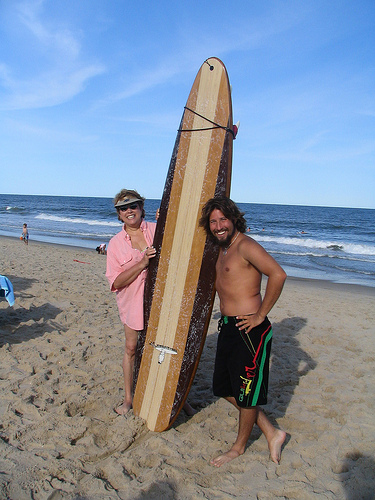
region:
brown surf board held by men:
[163, 56, 198, 415]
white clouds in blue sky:
[22, 7, 100, 72]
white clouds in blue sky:
[0, 60, 59, 114]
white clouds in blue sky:
[25, 114, 57, 159]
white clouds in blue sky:
[58, 100, 127, 163]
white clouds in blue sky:
[107, 41, 161, 110]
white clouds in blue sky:
[167, 9, 227, 49]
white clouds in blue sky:
[263, 8, 341, 75]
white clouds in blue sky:
[262, 71, 347, 154]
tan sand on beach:
[23, 419, 117, 474]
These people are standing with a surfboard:
[111, 46, 234, 344]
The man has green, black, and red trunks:
[218, 326, 280, 404]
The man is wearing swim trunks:
[211, 308, 289, 417]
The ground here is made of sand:
[10, 407, 176, 491]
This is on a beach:
[13, 329, 369, 495]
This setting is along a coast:
[13, 140, 339, 410]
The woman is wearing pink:
[82, 221, 188, 301]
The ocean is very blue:
[41, 192, 367, 292]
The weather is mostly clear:
[23, 6, 318, 153]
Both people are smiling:
[111, 197, 248, 260]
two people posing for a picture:
[72, 159, 297, 464]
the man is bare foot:
[193, 383, 301, 475]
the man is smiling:
[192, 186, 254, 258]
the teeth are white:
[208, 227, 235, 240]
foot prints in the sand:
[25, 396, 236, 496]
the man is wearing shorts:
[197, 292, 290, 425]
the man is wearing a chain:
[201, 225, 248, 264]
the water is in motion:
[278, 208, 353, 271]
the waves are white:
[291, 227, 364, 265]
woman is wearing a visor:
[89, 170, 154, 246]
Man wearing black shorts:
[209, 306, 277, 431]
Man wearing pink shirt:
[100, 222, 153, 339]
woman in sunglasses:
[113, 200, 146, 220]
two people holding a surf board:
[160, 131, 238, 357]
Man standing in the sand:
[199, 326, 295, 497]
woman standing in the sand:
[109, 306, 158, 429]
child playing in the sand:
[18, 221, 35, 251]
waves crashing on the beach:
[287, 226, 345, 292]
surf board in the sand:
[119, 360, 181, 462]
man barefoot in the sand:
[199, 377, 310, 484]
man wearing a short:
[200, 292, 287, 473]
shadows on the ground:
[282, 289, 349, 432]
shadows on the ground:
[141, 445, 365, 498]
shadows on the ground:
[199, 307, 332, 444]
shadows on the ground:
[255, 289, 307, 419]